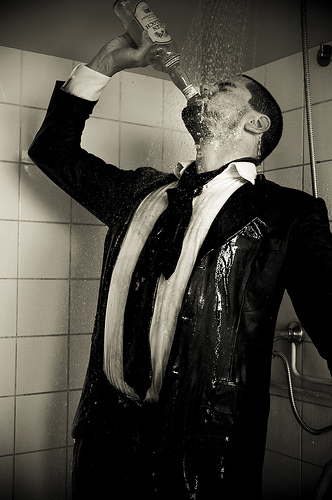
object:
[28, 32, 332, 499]
man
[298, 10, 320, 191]
hose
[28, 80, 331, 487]
jacket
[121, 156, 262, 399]
tie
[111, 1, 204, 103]
bottle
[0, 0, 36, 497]
wall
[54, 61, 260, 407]
shirt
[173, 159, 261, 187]
collar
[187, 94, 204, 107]
mouth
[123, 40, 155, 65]
thumb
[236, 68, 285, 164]
hair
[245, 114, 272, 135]
ear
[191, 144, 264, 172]
neck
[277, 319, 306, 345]
handle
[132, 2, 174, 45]
label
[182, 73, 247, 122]
face